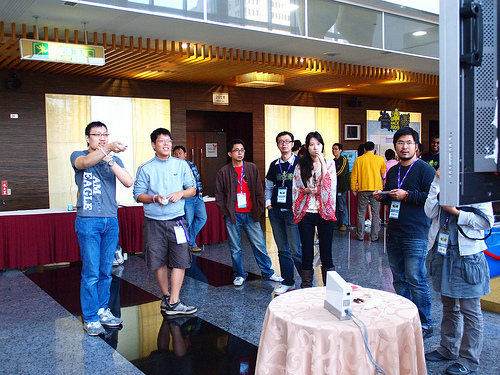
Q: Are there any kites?
A: No, there are no kites.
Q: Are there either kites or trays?
A: No, there are no kites or trays.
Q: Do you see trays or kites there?
A: No, there are no kites or trays.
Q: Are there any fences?
A: No, there are no fences.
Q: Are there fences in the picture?
A: No, there are no fences.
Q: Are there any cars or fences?
A: No, there are no fences or cars.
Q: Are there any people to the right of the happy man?
A: Yes, there is a person to the right of the man.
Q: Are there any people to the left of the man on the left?
A: No, the person is to the right of the man.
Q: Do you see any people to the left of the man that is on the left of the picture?
A: No, the person is to the right of the man.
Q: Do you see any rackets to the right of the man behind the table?
A: No, there is a person to the right of the man.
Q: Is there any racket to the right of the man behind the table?
A: No, there is a person to the right of the man.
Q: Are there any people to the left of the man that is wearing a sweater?
A: Yes, there is a person to the left of the man.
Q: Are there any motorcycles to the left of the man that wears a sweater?
A: No, there is a person to the left of the man.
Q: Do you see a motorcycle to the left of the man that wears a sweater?
A: No, there is a person to the left of the man.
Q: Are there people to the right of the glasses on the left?
A: Yes, there is a person to the right of the glasses.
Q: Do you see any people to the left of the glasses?
A: No, the person is to the right of the glasses.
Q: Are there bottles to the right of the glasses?
A: No, there is a person to the right of the glasses.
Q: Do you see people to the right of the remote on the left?
A: Yes, there is a person to the right of the remote.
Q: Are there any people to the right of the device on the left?
A: Yes, there is a person to the right of the remote.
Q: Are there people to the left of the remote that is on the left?
A: No, the person is to the right of the remote.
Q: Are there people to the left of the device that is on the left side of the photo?
A: No, the person is to the right of the remote.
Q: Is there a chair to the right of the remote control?
A: No, there is a person to the right of the remote control.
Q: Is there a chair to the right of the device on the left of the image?
A: No, there is a person to the right of the remote control.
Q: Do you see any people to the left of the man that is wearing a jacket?
A: Yes, there is a person to the left of the man.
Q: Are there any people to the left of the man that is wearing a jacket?
A: Yes, there is a person to the left of the man.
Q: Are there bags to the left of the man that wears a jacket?
A: No, there is a person to the left of the man.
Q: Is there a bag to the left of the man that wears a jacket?
A: No, there is a person to the left of the man.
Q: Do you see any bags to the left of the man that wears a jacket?
A: No, there is a person to the left of the man.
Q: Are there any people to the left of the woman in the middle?
A: Yes, there is a person to the left of the woman.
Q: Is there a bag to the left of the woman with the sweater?
A: No, there is a person to the left of the woman.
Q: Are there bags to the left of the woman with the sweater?
A: No, there is a person to the left of the woman.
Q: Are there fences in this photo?
A: No, there are no fences.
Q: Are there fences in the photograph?
A: No, there are no fences.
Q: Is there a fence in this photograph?
A: No, there are no fences.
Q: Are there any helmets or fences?
A: No, there are no fences or helmets.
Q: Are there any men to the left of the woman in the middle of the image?
A: Yes, there is a man to the left of the woman.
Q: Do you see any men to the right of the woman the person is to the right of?
A: No, the man is to the left of the woman.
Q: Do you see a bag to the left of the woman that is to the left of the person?
A: No, there is a man to the left of the woman.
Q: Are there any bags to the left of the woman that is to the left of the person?
A: No, there is a man to the left of the woman.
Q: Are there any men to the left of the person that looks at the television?
A: Yes, there is a man to the left of the person.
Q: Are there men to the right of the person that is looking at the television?
A: No, the man is to the left of the person.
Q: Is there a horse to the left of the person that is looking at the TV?
A: No, there is a man to the left of the person.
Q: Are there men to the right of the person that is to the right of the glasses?
A: Yes, there is a man to the right of the person.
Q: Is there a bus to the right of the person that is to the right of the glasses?
A: No, there is a man to the right of the person.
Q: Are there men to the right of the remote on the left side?
A: Yes, there is a man to the right of the remote control.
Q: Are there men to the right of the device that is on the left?
A: Yes, there is a man to the right of the remote control.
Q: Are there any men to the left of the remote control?
A: No, the man is to the right of the remote control.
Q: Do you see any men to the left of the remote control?
A: No, the man is to the right of the remote control.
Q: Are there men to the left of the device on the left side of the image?
A: No, the man is to the right of the remote control.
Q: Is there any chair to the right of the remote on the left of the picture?
A: No, there is a man to the right of the remote.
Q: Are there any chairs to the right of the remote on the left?
A: No, there is a man to the right of the remote.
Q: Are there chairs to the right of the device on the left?
A: No, there is a man to the right of the remote.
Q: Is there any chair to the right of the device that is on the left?
A: No, there is a man to the right of the remote.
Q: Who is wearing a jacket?
A: The man is wearing a jacket.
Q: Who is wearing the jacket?
A: The man is wearing a jacket.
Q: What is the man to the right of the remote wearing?
A: The man is wearing a jacket.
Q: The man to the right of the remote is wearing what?
A: The man is wearing a jacket.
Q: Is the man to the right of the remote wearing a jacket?
A: Yes, the man is wearing a jacket.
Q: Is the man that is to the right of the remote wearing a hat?
A: No, the man is wearing a jacket.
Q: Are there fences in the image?
A: No, there are no fences.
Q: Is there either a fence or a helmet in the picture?
A: No, there are no fences or helmets.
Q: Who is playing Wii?
A: The man is playing wii.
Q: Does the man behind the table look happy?
A: Yes, the man is happy.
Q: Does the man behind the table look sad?
A: No, the man is happy.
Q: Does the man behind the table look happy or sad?
A: The man is happy.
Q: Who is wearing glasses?
A: The man is wearing glasses.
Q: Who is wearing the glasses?
A: The man is wearing glasses.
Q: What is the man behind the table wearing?
A: The man is wearing glasses.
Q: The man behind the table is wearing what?
A: The man is wearing glasses.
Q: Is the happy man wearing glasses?
A: Yes, the man is wearing glasses.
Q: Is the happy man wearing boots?
A: No, the man is wearing glasses.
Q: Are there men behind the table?
A: Yes, there is a man behind the table.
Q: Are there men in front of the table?
A: No, the man is behind the table.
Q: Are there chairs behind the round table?
A: No, there is a man behind the table.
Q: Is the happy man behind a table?
A: Yes, the man is behind a table.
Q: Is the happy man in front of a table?
A: No, the man is behind a table.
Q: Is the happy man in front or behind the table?
A: The man is behind the table.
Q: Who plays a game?
A: The man plays a game.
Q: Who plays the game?
A: The man plays a game.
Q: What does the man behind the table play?
A: The man plays a game.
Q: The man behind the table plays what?
A: The man plays a game.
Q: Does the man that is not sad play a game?
A: Yes, the man plays a game.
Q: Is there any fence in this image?
A: No, there are no fences.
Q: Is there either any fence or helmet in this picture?
A: No, there are no fences or helmets.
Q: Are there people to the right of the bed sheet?
A: Yes, there is a person to the right of the bed sheet.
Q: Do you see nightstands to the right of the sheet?
A: No, there is a person to the right of the sheet.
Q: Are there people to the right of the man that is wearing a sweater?
A: Yes, there is a person to the right of the man.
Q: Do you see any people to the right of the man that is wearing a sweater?
A: Yes, there is a person to the right of the man.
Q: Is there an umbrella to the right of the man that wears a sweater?
A: No, there is a person to the right of the man.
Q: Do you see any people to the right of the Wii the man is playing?
A: Yes, there is a person to the right of the Wii.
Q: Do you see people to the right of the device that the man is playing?
A: Yes, there is a person to the right of the Wii.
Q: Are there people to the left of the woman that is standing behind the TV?
A: Yes, there is a person to the left of the woman.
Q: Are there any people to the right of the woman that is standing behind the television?
A: No, the person is to the left of the woman.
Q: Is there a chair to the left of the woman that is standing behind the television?
A: No, there is a person to the left of the woman.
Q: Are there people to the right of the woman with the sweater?
A: Yes, there is a person to the right of the woman.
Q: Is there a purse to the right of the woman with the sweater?
A: No, there is a person to the right of the woman.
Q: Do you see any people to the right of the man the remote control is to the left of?
A: Yes, there is a person to the right of the man.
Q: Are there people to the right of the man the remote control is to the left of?
A: Yes, there is a person to the right of the man.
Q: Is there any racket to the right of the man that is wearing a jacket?
A: No, there is a person to the right of the man.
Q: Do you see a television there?
A: Yes, there is a television.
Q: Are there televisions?
A: Yes, there is a television.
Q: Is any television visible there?
A: Yes, there is a television.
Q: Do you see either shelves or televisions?
A: Yes, there is a television.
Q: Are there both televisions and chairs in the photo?
A: No, there is a television but no chairs.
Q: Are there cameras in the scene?
A: No, there are no cameras.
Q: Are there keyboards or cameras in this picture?
A: No, there are no cameras or keyboards.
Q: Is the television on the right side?
A: Yes, the television is on the right of the image.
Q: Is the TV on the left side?
A: No, the TV is on the right of the image.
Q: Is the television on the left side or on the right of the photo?
A: The television is on the right of the image.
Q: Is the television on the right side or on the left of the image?
A: The television is on the right of the image.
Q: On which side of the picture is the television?
A: The television is on the right of the image.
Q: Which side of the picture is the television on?
A: The television is on the right of the image.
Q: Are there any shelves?
A: No, there are no shelves.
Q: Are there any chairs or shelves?
A: No, there are no shelves or chairs.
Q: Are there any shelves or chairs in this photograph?
A: No, there are no shelves or chairs.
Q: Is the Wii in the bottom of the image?
A: Yes, the Wii is in the bottom of the image.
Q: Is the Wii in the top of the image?
A: No, the Wii is in the bottom of the image.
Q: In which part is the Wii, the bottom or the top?
A: The Wii is in the bottom of the image.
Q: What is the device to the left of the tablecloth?
A: The device is a Wii.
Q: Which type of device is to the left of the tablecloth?
A: The device is a Wii.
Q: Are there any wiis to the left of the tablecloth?
A: Yes, there is a Wii to the left of the tablecloth.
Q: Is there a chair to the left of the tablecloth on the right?
A: No, there is a Wii to the left of the tablecloth.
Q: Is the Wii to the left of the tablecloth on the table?
A: Yes, the Wii is to the left of the tablecloth.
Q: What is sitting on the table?
A: The Wii is sitting on the table.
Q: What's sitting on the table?
A: The Wii is sitting on the table.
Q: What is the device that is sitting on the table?
A: The device is a Wii.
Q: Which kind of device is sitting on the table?
A: The device is a Wii.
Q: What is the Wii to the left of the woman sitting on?
A: The Wii is sitting on the table.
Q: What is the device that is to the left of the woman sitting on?
A: The Wii is sitting on the table.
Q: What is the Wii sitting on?
A: The Wii is sitting on the table.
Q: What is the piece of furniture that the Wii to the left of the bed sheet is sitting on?
A: The piece of furniture is a table.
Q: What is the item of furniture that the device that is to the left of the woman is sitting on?
A: The piece of furniture is a table.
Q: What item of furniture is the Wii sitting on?
A: The Wii is sitting on the table.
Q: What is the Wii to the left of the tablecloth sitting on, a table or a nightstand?
A: The Wii is sitting on a table.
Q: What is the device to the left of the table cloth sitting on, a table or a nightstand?
A: The Wii is sitting on a table.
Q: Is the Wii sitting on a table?
A: Yes, the Wii is sitting on a table.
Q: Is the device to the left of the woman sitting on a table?
A: Yes, the Wii is sitting on a table.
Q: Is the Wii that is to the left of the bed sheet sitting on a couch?
A: No, the Wii is sitting on a table.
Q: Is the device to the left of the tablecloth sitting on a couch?
A: No, the Wii is sitting on a table.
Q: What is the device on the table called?
A: The device is a Wii.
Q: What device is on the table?
A: The device is a Wii.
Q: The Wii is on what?
A: The Wii is on the table.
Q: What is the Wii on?
A: The Wii is on the table.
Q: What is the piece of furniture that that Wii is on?
A: The piece of furniture is a table.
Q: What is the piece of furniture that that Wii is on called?
A: The piece of furniture is a table.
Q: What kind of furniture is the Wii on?
A: The Wii is on the table.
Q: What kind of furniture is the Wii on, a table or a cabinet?
A: The Wii is on a table.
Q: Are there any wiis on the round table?
A: Yes, there is a Wii on the table.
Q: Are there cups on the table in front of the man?
A: No, there is a Wii on the table.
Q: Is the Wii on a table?
A: Yes, the Wii is on a table.